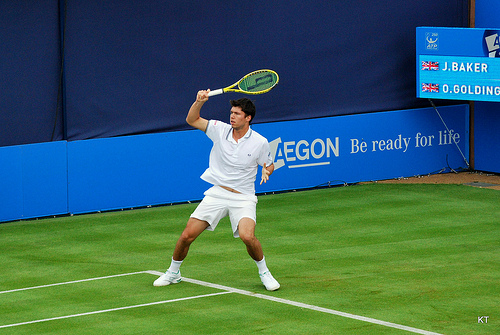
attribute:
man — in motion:
[152, 89, 279, 292]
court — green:
[2, 172, 497, 335]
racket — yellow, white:
[207, 68, 281, 97]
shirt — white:
[199, 117, 275, 196]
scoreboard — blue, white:
[414, 25, 499, 104]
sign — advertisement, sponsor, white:
[267, 126, 464, 175]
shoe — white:
[258, 269, 281, 291]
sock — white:
[254, 253, 268, 275]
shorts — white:
[190, 185, 260, 239]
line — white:
[145, 268, 439, 335]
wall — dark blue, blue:
[0, 0, 472, 149]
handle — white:
[206, 86, 224, 98]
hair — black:
[231, 97, 255, 125]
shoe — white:
[153, 268, 185, 288]